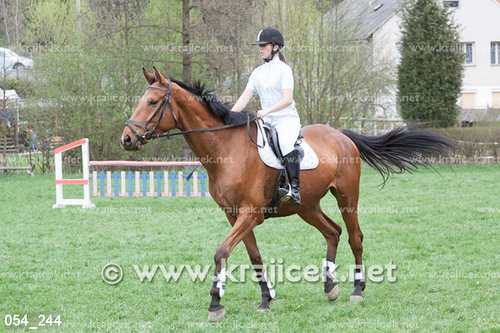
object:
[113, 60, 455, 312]
horse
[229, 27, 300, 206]
girl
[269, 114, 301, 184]
pants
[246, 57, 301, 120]
shirt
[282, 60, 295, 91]
short sleeve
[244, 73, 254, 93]
short sleeve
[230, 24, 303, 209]
woman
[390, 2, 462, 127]
tree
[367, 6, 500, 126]
white house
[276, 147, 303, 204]
boot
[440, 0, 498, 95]
wall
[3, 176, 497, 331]
grass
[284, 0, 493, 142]
building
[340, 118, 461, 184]
tail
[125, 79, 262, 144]
harness